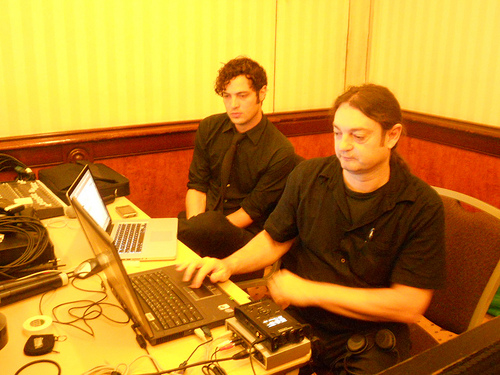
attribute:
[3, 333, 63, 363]
purse — black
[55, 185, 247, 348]
laptop — black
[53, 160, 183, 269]
laptop — on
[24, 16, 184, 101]
wall — yellow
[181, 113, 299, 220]
shirt — black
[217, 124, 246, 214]
tie — black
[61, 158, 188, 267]
laptop — on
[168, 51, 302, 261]
man — curly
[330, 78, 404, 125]
hair — long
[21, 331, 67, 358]
coin purse — black